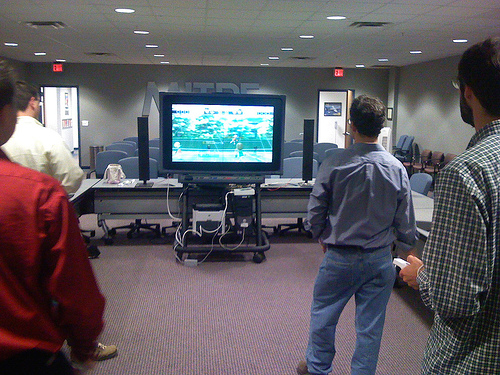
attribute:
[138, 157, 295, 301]
cart — black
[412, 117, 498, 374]
shirt — plaid, white, blue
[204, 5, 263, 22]
ceiling tile — white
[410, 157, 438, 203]
chair — brown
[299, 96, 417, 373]
man — dark 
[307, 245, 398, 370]
jeans — blue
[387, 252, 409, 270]
wii controller — white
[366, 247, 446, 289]
wii controller — white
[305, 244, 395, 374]
pants — blue jean, man's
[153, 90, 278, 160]
t.v — black, large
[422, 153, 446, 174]
chair — brown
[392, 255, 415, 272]
wii remote — pictured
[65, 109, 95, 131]
light switch — white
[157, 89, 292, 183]
tv — large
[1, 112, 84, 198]
shirt — white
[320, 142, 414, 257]
shirt — blue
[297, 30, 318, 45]
ceiling light — small 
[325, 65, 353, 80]
exit — red, white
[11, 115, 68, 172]
shirt — white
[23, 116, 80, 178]
shirt — white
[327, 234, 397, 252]
belt — black